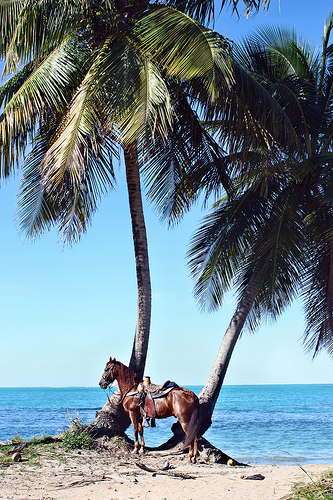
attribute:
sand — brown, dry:
[95, 443, 165, 492]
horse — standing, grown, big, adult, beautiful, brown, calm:
[97, 365, 220, 436]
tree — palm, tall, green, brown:
[39, 17, 238, 298]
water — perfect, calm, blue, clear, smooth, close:
[243, 382, 302, 485]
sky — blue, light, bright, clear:
[21, 247, 162, 372]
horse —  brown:
[98, 354, 199, 453]